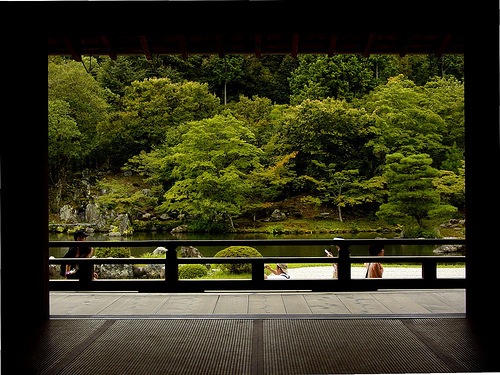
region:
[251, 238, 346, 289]
black wooden rails on porch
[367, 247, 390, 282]
woman in bathing suit walking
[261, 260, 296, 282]
man in tan hat taking picture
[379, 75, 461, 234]
bright green trees beside pond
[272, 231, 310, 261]
pond behind man taking picture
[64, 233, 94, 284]
couple in black posing for camera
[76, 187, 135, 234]
rocky cliff behind waters edge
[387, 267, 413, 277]
white sand at waters edge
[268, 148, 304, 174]
tree leaves turning yellow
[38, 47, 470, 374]
large wooden entrance to building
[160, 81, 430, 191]
these are trees at the far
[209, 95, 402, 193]
the trees are leafy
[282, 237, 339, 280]
this is a fence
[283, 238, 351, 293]
the fence is short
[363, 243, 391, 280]
this is a lady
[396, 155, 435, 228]
the leaves are green in color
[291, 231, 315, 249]
this is a water stream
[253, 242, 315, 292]
the fence is wooden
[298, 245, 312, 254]
the water is calm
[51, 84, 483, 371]
the door is wide open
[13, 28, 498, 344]
A doorway near a lake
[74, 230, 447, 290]
A fence near a lake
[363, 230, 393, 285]
A woman beyond the fence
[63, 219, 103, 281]
People beyond the fence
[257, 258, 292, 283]
a person taking a picture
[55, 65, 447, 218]
Trees in the distance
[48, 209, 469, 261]
A lake near the trees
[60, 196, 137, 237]
rocks near the lake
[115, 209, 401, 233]
the far shore of the lake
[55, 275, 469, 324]
a walkway near the fence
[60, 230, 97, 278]
a man sitting out side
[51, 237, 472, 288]
a wooden dark rail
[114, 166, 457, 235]
trees on the bank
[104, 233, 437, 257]
green water in a stream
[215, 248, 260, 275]
a round bush by water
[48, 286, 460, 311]
a gray wooden floor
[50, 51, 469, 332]
a door opening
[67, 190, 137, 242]
gray rocks on the bank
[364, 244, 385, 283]
a woman walking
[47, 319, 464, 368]
strip carpet on the floor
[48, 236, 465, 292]
a black railing by the road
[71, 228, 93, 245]
the head of a person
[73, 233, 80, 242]
the ear of a person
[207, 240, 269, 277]
a small green bush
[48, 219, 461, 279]
a calm pond of water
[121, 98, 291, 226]
a large green tree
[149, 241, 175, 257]
a gray rock on the shore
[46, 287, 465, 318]
a gray cement sidwalk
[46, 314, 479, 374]
a grooved path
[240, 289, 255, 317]
a crack in the sidewalk